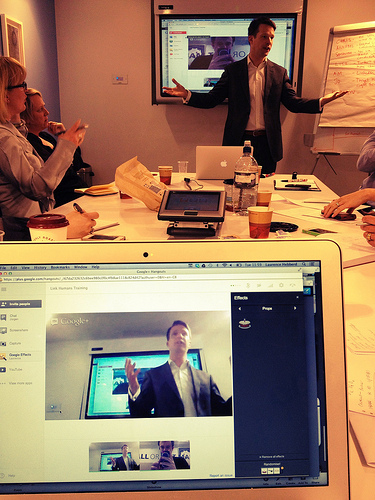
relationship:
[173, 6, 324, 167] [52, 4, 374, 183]
man near wall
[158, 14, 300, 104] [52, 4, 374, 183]
screen on wall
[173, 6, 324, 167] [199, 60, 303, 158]
man wearing suit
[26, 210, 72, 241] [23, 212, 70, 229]
cup has lid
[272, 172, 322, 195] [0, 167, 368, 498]
clipboard on top of table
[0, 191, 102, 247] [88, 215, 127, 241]
person writing on paper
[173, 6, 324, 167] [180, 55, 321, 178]
man wearing wedding band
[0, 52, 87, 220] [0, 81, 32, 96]
woman wearing glasses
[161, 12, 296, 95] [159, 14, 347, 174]
screen behind speaker